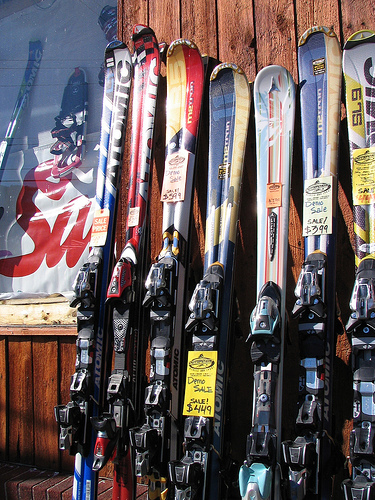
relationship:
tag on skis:
[178, 347, 223, 425] [162, 58, 250, 497]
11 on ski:
[209, 87, 244, 122] [168, 61, 251, 498]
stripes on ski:
[130, 22, 161, 498] [106, 20, 142, 498]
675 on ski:
[89, 205, 123, 245] [81, 37, 293, 474]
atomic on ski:
[104, 59, 133, 193] [101, 45, 124, 247]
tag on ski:
[178, 347, 223, 425] [180, 66, 246, 404]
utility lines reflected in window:
[1, 55, 105, 89] [5, 2, 135, 302]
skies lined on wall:
[56, 31, 374, 495] [1, 0, 373, 498]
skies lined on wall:
[56, 31, 374, 495] [114, 2, 368, 498]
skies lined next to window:
[56, 31, 374, 495] [0, 1, 114, 297]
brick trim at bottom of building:
[4, 431, 134, 498] [1, 1, 372, 496]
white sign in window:
[9, 93, 74, 285] [3, 12, 105, 297]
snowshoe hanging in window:
[46, 65, 88, 178] [0, 0, 116, 338]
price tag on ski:
[261, 179, 283, 212] [234, 58, 297, 498]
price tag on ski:
[89, 205, 116, 252] [50, 39, 135, 498]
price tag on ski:
[89, 205, 116, 252] [89, 31, 129, 229]